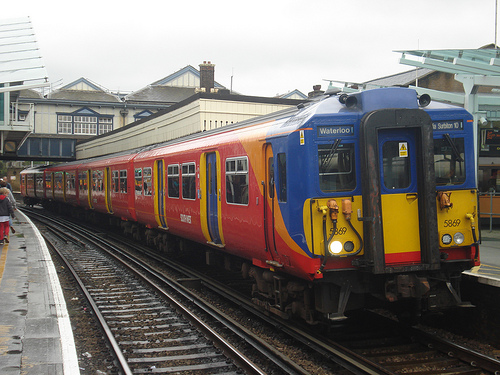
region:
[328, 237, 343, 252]
Headlight on a train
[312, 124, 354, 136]
Word Waterloo on a train sign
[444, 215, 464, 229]
Number 5869 on a train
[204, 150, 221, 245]
Blue door on a train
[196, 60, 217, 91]
Chimney on a building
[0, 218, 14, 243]
Person wearing red pants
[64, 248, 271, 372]
Train tracks at a staion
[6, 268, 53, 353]
Grey bricks on a platform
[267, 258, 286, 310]
Small ladder on a train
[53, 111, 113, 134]
Window on front of building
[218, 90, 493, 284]
The train is blue, yellow and red.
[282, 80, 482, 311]
The front of the train is flat.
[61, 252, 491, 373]
Two pairs of train tracks.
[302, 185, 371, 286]
One light is lit on the train.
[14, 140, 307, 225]
Windows are on the train.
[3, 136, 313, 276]
Doors are on the train.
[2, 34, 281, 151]
Buildings are in the background.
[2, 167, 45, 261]
People are on the platform.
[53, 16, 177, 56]
The sky is overcast.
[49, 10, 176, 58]
The sky is cloudy.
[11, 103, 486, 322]
One train on the tracks.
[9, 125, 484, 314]
The train is a passenger train.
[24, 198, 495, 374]
Tracks are made of metal.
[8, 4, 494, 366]
Photo taken during the day.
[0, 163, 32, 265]
People standing on the platform.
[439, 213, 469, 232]
Train number 5869.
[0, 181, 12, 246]
Child wearing red pants.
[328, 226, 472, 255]
Two headlights on the front.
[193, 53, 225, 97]
Brick chimney sticking up from the building in back.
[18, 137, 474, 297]
The train is red.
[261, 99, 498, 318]
The train is blue and yellow.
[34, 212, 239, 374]
The train track is clear.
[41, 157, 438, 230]
People are on the track.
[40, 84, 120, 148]
The building is white.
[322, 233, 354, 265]
The light is on.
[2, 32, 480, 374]
The train is colorful.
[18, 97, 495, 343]
The train station is by buildings.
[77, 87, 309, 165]
The building is tan.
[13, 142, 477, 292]
The tain is large.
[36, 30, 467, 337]
colorful train leaving station on cloudy day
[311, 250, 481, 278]
red stripe on bottom front of train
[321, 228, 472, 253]
trains has two headlights on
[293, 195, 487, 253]
yellow strip is in the middle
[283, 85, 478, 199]
blue stripe on top of front of train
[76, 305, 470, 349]
two sets of train tracks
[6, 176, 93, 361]
cement train platform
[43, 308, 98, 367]
edge is painted white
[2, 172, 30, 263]
people are walking in the distance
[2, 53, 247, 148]
tops of houses or small buildings in background